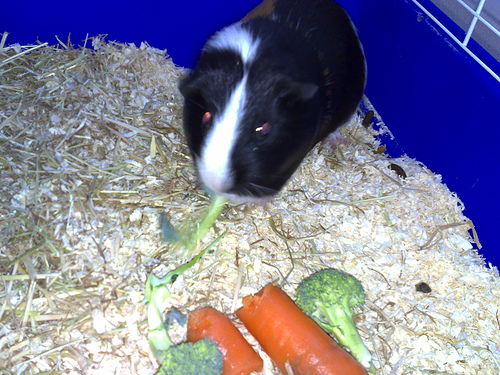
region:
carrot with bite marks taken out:
[230, 256, 313, 373]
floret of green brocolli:
[300, 252, 376, 354]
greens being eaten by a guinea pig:
[180, 172, 225, 249]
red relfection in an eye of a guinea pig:
[197, 108, 217, 128]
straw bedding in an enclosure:
[22, 66, 135, 256]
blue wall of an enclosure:
[386, 31, 467, 157]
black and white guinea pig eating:
[186, 36, 333, 241]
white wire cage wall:
[426, 2, 498, 69]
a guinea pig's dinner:
[125, 264, 375, 374]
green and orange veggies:
[159, 265, 349, 373]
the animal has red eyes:
[200, 113, 271, 137]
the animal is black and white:
[184, 3, 367, 205]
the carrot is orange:
[188, 284, 364, 371]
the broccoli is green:
[148, 273, 369, 370]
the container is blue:
[0, 0, 499, 274]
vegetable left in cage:
[146, 271, 375, 373]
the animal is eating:
[167, 193, 224, 251]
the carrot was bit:
[236, 282, 271, 314]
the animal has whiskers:
[176, 166, 310, 229]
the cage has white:
[415, 0, 497, 82]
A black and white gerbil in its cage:
[15, 0, 490, 362]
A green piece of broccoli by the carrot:
[294, 258, 378, 355]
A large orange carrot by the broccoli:
[247, 290, 361, 373]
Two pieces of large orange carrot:
[195, 299, 344, 371]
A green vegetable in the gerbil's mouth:
[175, 194, 255, 271]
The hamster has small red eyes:
[190, 99, 283, 146]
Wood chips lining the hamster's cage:
[35, 79, 152, 259]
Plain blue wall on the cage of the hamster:
[387, 40, 497, 152]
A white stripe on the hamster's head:
[204, 83, 266, 188]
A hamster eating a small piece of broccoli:
[142, 0, 385, 248]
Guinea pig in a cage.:
[173, 0, 422, 246]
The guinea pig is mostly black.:
[194, 2, 376, 207]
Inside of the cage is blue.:
[14, 1, 497, 231]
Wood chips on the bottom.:
[392, 231, 499, 353]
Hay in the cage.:
[4, 69, 154, 192]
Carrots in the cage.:
[184, 298, 333, 373]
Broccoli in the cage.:
[284, 255, 387, 353]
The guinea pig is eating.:
[151, 160, 262, 270]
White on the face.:
[194, 80, 254, 196]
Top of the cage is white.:
[417, 0, 499, 77]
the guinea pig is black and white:
[163, 11, 381, 203]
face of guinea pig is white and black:
[190, 67, 270, 197]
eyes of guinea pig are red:
[195, 100, 270, 135]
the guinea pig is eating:
[146, 5, 357, 247]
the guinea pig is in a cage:
[6, 5, 486, 372]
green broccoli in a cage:
[281, 255, 376, 362]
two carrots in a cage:
[185, 280, 360, 365]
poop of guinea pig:
[351, 105, 456, 307]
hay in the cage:
[1, 40, 191, 326]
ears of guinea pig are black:
[172, 65, 313, 110]